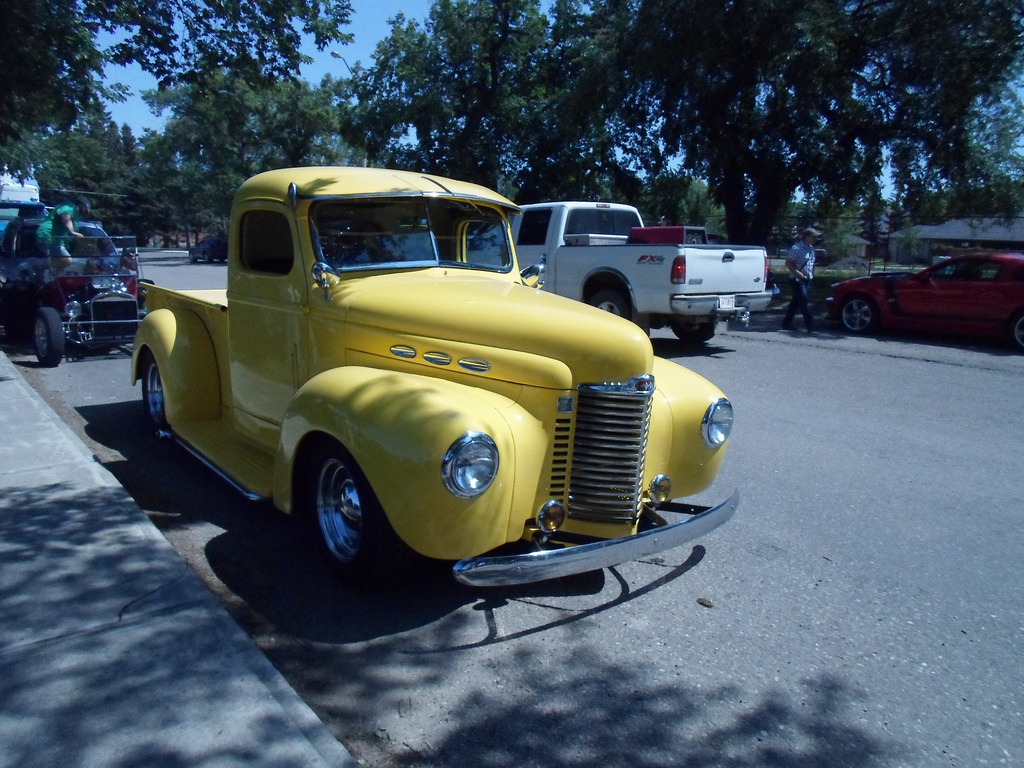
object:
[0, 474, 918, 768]
shadow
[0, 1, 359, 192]
tree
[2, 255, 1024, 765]
pavement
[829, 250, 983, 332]
side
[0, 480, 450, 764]
tree shadow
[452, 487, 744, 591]
vehicle bumper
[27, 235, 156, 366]
front end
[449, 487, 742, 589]
part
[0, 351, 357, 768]
sidewalk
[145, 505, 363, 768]
curb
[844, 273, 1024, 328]
stripe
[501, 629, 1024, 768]
ground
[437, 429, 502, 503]
headlight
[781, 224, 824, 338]
man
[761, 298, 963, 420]
road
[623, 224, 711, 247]
dog cage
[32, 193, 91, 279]
person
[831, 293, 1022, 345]
bottom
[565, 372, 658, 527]
silver grill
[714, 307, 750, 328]
tag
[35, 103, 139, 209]
trees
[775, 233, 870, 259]
cars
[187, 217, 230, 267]
car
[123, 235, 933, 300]
road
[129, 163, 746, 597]
classic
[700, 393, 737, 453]
headlight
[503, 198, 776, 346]
truck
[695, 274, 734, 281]
newer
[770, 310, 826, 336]
walking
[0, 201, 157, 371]
car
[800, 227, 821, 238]
cap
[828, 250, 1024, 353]
car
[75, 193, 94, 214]
hat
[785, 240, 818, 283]
shirt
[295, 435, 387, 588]
tire